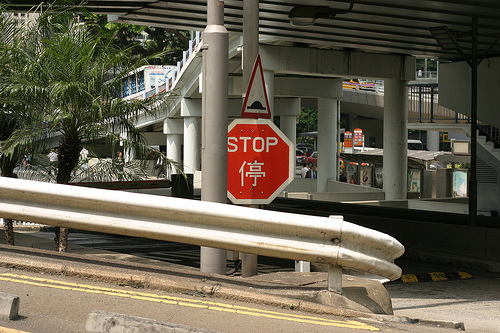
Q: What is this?
A: A road.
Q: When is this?
A: Daytime.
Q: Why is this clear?
A: To be seen.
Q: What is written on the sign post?
A: Stop.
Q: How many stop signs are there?
A: One.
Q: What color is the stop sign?
A: Red.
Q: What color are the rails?
A: Silver.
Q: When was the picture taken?
A: Daytime.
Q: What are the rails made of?
A: Metal.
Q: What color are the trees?
A: Green.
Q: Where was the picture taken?
A: On the street.